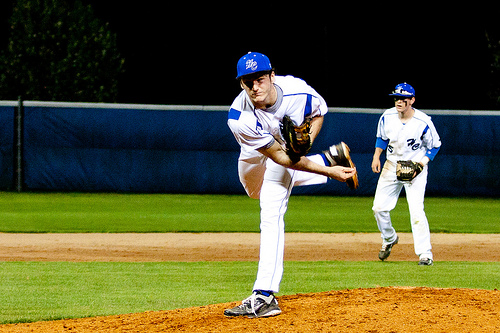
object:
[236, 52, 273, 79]
cap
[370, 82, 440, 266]
player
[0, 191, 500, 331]
field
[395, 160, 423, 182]
mit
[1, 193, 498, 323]
grass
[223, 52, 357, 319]
player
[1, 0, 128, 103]
tree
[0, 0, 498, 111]
net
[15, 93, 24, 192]
post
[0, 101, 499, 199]
fence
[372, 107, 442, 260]
uniform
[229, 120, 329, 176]
arm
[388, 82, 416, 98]
hat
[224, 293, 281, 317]
sneaker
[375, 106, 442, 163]
shirt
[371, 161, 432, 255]
pants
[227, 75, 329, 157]
jersey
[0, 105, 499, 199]
padding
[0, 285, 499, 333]
mound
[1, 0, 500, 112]
sky